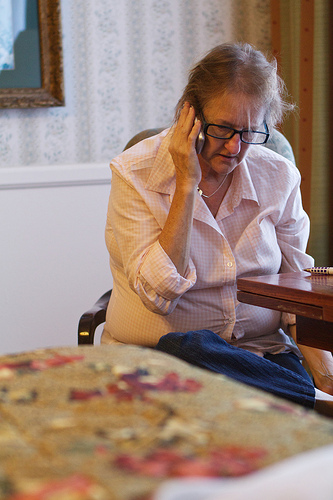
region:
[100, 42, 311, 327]
old woman on phone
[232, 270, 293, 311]
corner of wood table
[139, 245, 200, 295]
rolled up sleeve on shirt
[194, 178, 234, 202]
jewelry on woman's neck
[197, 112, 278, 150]
black glasses on face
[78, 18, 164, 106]
wallpaper on back wall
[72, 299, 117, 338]
curved arm of chair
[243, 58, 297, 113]
messy hair on head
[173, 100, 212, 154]
hand on silver phone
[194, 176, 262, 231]
open collar of shirt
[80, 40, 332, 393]
a woman wearing glasses talking on the phone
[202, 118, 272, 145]
a woman's pair of black framed glasses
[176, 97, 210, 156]
a silver colored cell phone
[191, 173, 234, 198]
a woman's silver colored necklace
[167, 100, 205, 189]
a woman's right hand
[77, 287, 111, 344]
the arm of a brown wooden chair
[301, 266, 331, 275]
a white and blue fountain pen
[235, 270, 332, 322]
a brown wooden table top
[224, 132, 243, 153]
an old woman's nose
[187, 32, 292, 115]
a woman's brown hair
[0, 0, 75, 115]
A picture in a frame.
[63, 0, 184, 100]
Wallpaper.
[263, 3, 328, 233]
A striped curtain.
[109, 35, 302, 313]
The woman is talking on a cellphone.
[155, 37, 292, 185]
The woman is wearing glasses.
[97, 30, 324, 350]
The woman is wearing a gingham shirt.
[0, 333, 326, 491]
A tablecloth.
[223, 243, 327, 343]
A wood table.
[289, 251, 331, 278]
A pen is on the table.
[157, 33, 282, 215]
The woman is wearing a necklace.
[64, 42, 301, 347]
woman sitting on chair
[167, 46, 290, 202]
black framed glasses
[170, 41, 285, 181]
woman holding cell phone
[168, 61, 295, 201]
woman with necklace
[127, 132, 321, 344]
pink and white checked shirt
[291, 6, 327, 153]
orange stripe with dots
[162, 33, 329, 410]
woman wearing blue pants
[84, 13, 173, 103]
white and blue printed wallpaper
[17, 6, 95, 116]
part of picture frame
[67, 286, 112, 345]
brown wooden arm of chair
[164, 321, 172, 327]
a strip on a shirt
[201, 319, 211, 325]
a strip on a shirt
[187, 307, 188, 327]
a strip on a shirt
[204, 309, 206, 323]
a strip on a shirt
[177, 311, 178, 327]
a strip on a shirt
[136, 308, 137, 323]
a strip on a shirt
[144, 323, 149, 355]
a strip on a shirt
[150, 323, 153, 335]
a strip on a shirt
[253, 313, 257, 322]
a strip on a shirt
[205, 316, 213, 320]
a strip on a shirt